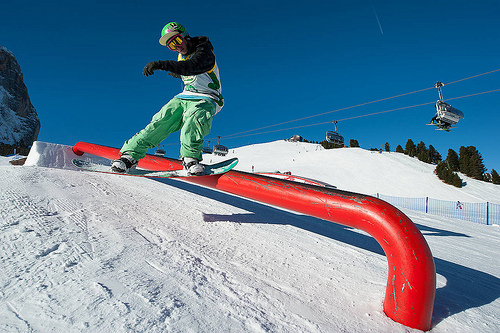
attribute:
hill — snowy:
[216, 139, 498, 214]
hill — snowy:
[200, 137, 495, 332]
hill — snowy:
[0, 146, 493, 330]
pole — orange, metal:
[72, 139, 437, 331]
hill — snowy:
[203, 139, 498, 208]